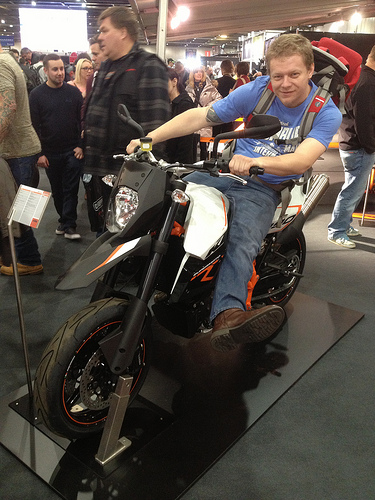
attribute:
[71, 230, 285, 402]
motorcycle — black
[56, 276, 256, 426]
motorcycle — black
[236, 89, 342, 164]
top — black and gray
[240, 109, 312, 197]
shirt — blue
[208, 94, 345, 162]
shirt — blue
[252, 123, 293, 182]
print — white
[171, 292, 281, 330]
left shoe — brown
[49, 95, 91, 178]
outfit — black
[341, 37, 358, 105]
backpack — red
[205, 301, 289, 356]
boot — brown, leather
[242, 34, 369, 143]
backpack — red, black, grey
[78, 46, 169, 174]
shirt — striped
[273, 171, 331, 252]
tail pipe — silver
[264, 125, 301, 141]
writing — white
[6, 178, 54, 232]
sign — white, informational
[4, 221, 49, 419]
pole — black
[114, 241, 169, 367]
frame — black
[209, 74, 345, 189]
shirt — blue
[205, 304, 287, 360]
shoe — brown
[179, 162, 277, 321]
jeans — blue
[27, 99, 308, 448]
bike — orange, black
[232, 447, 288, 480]
floor — small, black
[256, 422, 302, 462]
floor — small, black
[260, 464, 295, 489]
floor — small, black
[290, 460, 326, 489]
floor — small, black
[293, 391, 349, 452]
floor — small, black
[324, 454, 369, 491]
floor — small, black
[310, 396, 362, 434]
floor — small, black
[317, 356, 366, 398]
floor — small, black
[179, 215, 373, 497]
floor — small, part, black